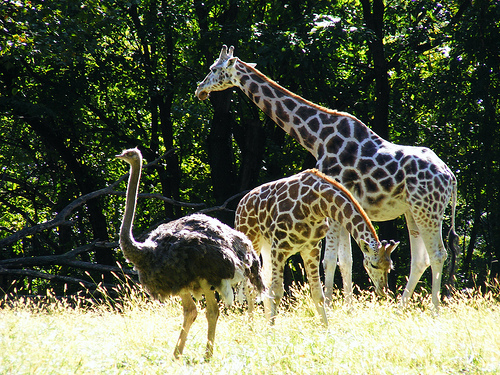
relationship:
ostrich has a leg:
[113, 146, 267, 366] [196, 275, 218, 363]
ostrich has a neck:
[113, 146, 267, 366] [118, 161, 142, 264]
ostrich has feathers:
[113, 146, 267, 366] [167, 234, 275, 304]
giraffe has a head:
[193, 41, 458, 310] [196, 43, 258, 101]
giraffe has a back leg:
[193, 41, 458, 310] [409, 192, 455, 313]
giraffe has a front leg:
[193, 41, 458, 310] [316, 168, 342, 303]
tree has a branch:
[1, 6, 116, 307] [17, 102, 55, 164]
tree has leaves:
[1, 6, 116, 307] [31, 39, 91, 91]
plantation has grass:
[7, 0, 491, 374] [7, 289, 497, 370]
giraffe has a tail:
[193, 41, 458, 310] [447, 168, 462, 240]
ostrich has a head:
[113, 146, 267, 366] [112, 143, 148, 179]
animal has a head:
[234, 166, 401, 329] [358, 237, 402, 300]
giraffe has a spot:
[193, 41, 458, 310] [321, 127, 346, 161]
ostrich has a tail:
[113, 146, 267, 366] [228, 221, 270, 301]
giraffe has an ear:
[193, 41, 458, 310] [214, 41, 230, 62]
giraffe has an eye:
[193, 41, 458, 310] [210, 66, 218, 76]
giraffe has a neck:
[193, 41, 458, 310] [244, 64, 340, 164]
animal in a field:
[193, 41, 458, 310] [7, 289, 497, 370]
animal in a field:
[113, 146, 267, 366] [7, 289, 497, 370]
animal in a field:
[225, 166, 398, 326] [7, 289, 497, 370]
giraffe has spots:
[193, 41, 458, 310] [319, 123, 338, 145]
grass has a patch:
[7, 289, 497, 370] [51, 314, 141, 362]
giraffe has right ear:
[193, 41, 458, 310] [228, 45, 234, 56]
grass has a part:
[7, 289, 497, 370] [28, 305, 116, 364]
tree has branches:
[1, 6, 116, 307] [32, 51, 95, 131]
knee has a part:
[200, 302, 227, 330] [212, 309, 222, 321]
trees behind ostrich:
[1, 6, 116, 307] [113, 146, 267, 366]